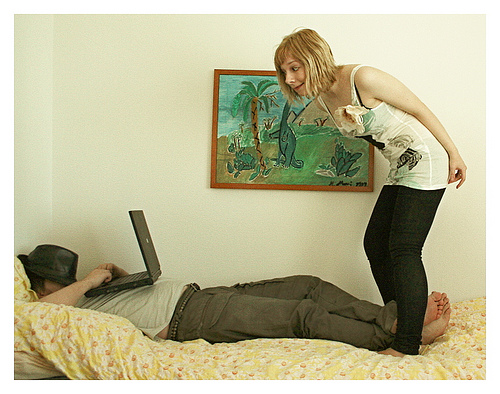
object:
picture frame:
[200, 65, 377, 197]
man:
[16, 243, 453, 354]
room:
[51, 22, 489, 305]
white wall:
[5, 17, 485, 300]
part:
[53, 14, 200, 158]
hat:
[17, 244, 79, 285]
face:
[278, 54, 320, 97]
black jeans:
[362, 180, 446, 355]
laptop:
[83, 208, 160, 300]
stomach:
[100, 287, 151, 320]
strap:
[344, 62, 364, 106]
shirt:
[309, 67, 452, 189]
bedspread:
[15, 256, 478, 383]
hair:
[21, 267, 43, 286]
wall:
[19, 15, 493, 297]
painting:
[212, 67, 374, 194]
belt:
[165, 281, 200, 340]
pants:
[168, 274, 394, 352]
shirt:
[71, 275, 189, 340]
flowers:
[199, 337, 321, 380]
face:
[34, 275, 62, 291]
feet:
[419, 291, 452, 343]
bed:
[14, 259, 489, 389]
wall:
[15, 29, 48, 225]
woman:
[269, 27, 466, 357]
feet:
[419, 292, 452, 347]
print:
[95, 348, 402, 381]